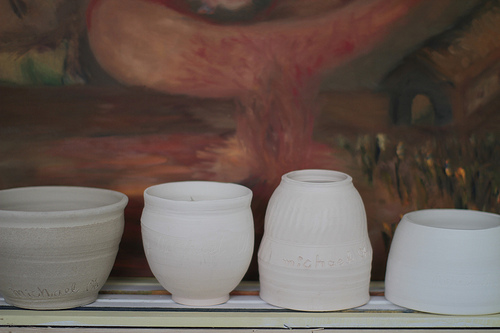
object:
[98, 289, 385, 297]
stripe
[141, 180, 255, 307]
bowls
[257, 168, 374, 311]
bowls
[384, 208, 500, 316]
bowls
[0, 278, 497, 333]
fixture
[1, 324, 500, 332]
stripe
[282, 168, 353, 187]
bottom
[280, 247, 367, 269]
name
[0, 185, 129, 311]
beige bowl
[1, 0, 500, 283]
painting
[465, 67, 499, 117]
window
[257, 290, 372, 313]
base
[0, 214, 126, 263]
ribbed circles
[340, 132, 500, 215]
vegetation